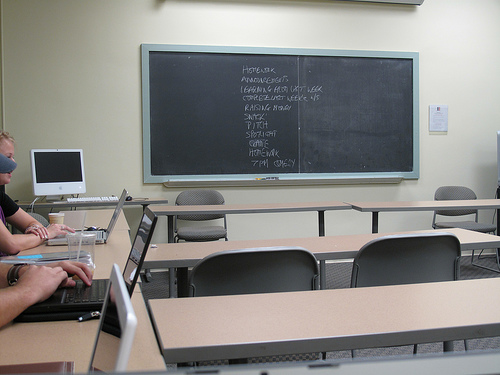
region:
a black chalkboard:
[71, 17, 451, 207]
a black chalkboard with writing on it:
[132, 35, 433, 203]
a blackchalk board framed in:
[114, 15, 495, 227]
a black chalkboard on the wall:
[104, 27, 430, 188]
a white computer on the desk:
[14, 130, 136, 215]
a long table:
[154, 286, 497, 342]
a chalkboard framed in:
[107, 34, 423, 181]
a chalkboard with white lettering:
[121, 20, 423, 183]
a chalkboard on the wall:
[103, 12, 442, 184]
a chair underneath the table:
[177, 229, 335, 319]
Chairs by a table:
[178, 241, 468, 286]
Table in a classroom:
[152, 280, 408, 353]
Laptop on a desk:
[13, 181, 178, 300]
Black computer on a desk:
[31, 206, 175, 303]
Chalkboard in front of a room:
[156, 36, 408, 190]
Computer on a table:
[20, 133, 137, 211]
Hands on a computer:
[9, 252, 105, 322]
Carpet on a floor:
[313, 238, 495, 365]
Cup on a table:
[43, 207, 68, 234]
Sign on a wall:
[428, 100, 461, 137]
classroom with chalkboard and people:
[1, 38, 489, 355]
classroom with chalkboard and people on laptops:
[5, 27, 480, 330]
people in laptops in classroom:
[0, 101, 151, 368]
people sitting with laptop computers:
[0, 95, 171, 367]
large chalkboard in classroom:
[113, 20, 427, 188]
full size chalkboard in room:
[124, 36, 424, 188]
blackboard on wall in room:
[117, 25, 427, 192]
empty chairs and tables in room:
[133, 180, 489, 357]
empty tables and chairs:
[140, 178, 480, 346]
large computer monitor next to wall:
[22, 134, 94, 203]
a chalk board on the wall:
[121, 27, 431, 185]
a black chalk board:
[119, 17, 429, 189]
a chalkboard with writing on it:
[102, 18, 452, 189]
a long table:
[150, 280, 499, 335]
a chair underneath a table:
[176, 250, 331, 305]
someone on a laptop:
[2, 205, 171, 317]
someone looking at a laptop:
[4, 129, 129, 254]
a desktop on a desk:
[12, 130, 147, 222]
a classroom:
[11, 10, 496, 367]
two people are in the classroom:
[3, 122, 158, 351]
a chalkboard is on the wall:
[140, 40, 425, 193]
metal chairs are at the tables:
[148, 189, 498, 355]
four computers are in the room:
[28, 142, 163, 373]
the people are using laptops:
[1, 132, 156, 324]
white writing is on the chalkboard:
[143, 47, 430, 182]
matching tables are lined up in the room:
[34, 177, 499, 372]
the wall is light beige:
[25, 6, 498, 231]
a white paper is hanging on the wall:
[426, 102, 451, 137]